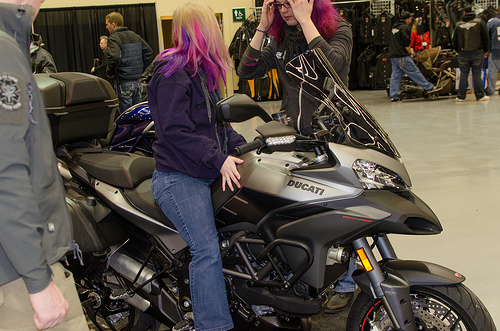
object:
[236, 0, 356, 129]
friends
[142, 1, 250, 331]
friends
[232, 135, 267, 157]
handle bar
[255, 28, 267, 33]
wristband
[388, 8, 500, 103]
people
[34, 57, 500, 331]
cycle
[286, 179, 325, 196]
gazelles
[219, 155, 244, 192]
hand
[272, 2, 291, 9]
glasses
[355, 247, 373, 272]
street sign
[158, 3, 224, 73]
hair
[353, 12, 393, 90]
shirts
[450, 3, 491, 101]
man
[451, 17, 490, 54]
jacket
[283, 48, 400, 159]
bike windshield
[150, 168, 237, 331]
jeans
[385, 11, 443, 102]
man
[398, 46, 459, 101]
stroller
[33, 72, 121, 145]
helmet box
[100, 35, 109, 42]
coffee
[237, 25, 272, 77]
arm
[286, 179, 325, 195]
logo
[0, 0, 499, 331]
motor convention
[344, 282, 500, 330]
tire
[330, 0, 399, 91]
rack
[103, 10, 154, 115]
man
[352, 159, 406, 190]
headlight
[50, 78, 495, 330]
bike